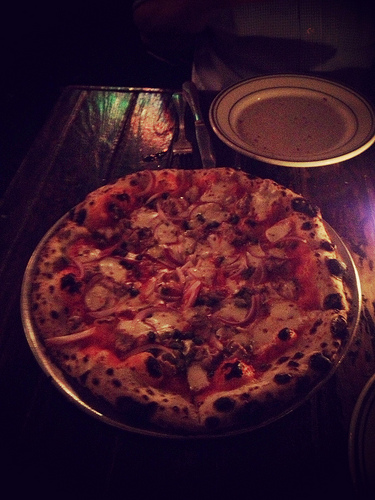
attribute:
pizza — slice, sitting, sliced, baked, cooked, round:
[17, 163, 357, 442]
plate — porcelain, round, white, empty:
[202, 68, 373, 174]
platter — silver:
[14, 208, 371, 447]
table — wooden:
[1, 77, 370, 484]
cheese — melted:
[80, 292, 128, 311]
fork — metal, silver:
[166, 90, 197, 160]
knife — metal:
[181, 77, 219, 171]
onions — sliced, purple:
[241, 247, 267, 325]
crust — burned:
[194, 339, 336, 428]